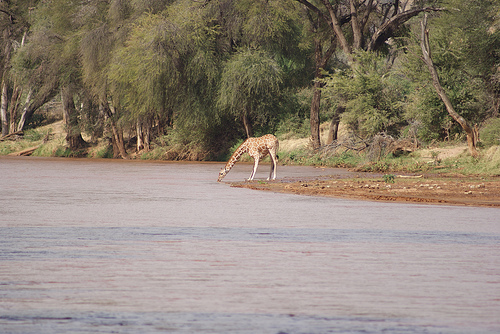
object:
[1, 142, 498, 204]
lake edge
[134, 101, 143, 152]
tree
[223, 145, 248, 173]
neck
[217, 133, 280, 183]
giraffe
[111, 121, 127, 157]
trunk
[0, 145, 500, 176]
edge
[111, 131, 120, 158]
trunk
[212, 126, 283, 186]
telephone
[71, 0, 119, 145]
tree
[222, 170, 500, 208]
dirt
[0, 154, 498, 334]
lake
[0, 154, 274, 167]
dirt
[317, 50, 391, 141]
tree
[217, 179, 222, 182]
mouth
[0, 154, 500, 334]
water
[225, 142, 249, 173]
giraffe's neck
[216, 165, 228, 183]
head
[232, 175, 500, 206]
muddy ground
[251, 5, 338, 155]
tree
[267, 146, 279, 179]
back legs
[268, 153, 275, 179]
back legs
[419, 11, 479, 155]
tree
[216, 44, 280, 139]
tree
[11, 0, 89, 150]
tree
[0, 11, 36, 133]
tree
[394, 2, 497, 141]
tree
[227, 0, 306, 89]
tree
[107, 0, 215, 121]
green tree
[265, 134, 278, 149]
butt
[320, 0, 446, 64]
tree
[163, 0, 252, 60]
trees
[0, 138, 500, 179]
shore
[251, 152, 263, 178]
leg